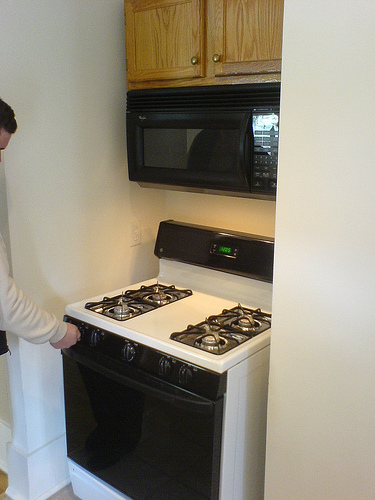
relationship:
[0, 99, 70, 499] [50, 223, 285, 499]
man near stove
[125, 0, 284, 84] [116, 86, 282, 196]
cabinet above microwave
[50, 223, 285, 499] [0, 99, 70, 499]
stove near man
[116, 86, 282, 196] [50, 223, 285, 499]
microwave above stove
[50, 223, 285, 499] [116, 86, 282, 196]
stove below microwave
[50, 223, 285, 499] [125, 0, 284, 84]
stove below cabinet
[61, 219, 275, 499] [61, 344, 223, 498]
stove has door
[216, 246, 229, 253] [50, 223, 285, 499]
clock in stove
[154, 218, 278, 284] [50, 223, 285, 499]
part of stove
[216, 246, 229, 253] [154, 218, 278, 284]
clock in part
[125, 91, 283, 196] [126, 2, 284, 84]
microwave under cabinet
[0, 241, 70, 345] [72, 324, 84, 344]
arm turning dial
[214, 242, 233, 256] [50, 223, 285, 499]
display on stove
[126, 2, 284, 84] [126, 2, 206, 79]
cabinet has door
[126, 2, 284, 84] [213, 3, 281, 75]
cabinet has door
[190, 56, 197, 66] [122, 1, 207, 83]
knob on door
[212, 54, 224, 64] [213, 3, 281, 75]
knob on door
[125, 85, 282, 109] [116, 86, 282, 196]
vent for microwave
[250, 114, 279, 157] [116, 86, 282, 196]
daylight off microwave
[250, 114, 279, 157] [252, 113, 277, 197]
daylight off control panel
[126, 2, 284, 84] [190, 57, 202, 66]
cabinet with knob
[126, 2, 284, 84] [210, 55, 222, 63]
cabinet with knob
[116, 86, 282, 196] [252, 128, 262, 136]
microwave with button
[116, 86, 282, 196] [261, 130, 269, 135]
microwave with button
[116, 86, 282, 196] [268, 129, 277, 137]
microwave with button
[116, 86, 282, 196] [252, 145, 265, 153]
microwave with button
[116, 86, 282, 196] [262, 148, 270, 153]
microwave with button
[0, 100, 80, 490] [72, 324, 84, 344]
person using dial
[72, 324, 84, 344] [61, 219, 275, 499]
dial on stove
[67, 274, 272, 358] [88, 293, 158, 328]
stove top has burner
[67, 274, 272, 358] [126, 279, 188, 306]
stove top has burner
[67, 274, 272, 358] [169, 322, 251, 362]
stove top has burner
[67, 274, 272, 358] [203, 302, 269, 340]
stove top has burner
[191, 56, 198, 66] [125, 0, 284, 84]
knob for cabinet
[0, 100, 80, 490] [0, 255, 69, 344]
person wearing shirt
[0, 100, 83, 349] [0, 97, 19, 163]
person has head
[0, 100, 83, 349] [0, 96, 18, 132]
person with hair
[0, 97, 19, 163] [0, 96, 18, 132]
head with hair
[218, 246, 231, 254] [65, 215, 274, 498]
clock on oven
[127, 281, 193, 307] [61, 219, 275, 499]
burner on stove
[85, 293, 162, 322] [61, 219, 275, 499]
burner on stove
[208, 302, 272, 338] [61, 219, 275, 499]
burner on stove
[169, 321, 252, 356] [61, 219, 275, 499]
burner on stove